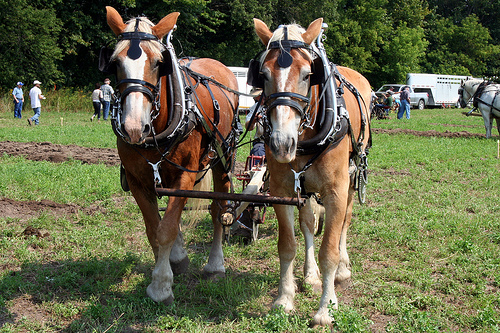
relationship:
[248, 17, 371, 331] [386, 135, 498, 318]
horse on field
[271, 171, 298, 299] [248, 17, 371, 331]
leg of horse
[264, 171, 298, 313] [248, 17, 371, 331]
leg of horse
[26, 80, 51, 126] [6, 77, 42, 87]
man wearing caps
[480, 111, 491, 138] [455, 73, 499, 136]
leg of horse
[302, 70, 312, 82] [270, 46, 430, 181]
eye of horse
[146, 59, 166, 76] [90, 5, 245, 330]
eye of horse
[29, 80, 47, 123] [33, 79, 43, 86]
man wearing caps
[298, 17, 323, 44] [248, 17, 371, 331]
ear of horse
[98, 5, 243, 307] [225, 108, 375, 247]
horse pulling cart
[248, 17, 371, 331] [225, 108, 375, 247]
horse pulling cart